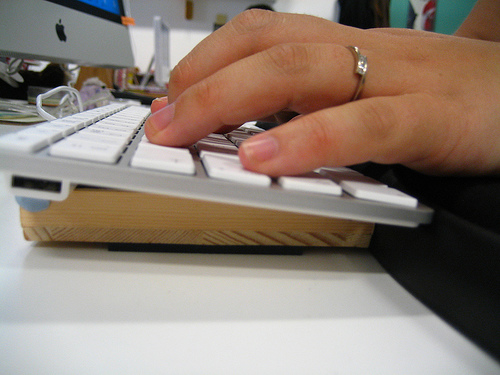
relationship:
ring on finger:
[346, 38, 374, 93] [235, 96, 467, 176]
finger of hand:
[235, 96, 467, 176] [140, 15, 494, 166]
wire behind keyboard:
[35, 86, 82, 116] [3, 96, 435, 248]